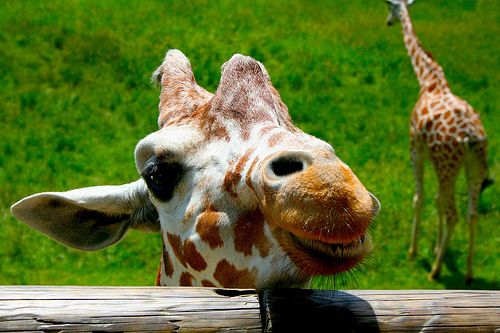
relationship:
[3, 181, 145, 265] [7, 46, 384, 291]
ear on giraffe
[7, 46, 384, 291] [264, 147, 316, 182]
giraffe has nostril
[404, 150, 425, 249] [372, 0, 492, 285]
leg on giraffe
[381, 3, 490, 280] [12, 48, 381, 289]
giraffe leaning head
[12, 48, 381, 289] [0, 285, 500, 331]
head over fence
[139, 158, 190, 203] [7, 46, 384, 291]
eye of giraffe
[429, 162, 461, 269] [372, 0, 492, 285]
leg of a giraffe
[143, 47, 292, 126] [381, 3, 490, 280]
horns of giraffe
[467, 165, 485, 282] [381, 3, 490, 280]
leg of giraffe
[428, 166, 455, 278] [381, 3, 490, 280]
leg of giraffe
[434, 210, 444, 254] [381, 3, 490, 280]
leg of giraffe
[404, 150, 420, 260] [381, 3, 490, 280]
leg of giraffe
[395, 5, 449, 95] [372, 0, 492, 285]
neck of giraffe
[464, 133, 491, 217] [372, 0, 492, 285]
tail of giraffe